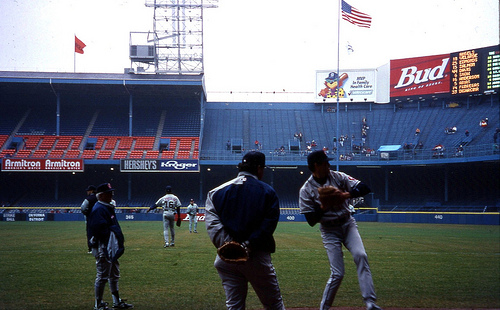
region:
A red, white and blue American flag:
[338, 0, 378, 33]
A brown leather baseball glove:
[212, 238, 253, 268]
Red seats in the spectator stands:
[2, 130, 204, 165]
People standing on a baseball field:
[2, 143, 499, 308]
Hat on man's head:
[303, 145, 337, 179]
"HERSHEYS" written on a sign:
[120, 154, 160, 176]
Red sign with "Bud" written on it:
[388, 51, 452, 101]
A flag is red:
[68, 28, 90, 75]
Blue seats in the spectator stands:
[202, 101, 498, 161]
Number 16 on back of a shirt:
[161, 197, 180, 216]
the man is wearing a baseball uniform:
[188, 140, 423, 302]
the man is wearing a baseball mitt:
[202, 222, 262, 299]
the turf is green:
[372, 232, 450, 295]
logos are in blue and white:
[121, 154, 216, 206]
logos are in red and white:
[6, 154, 125, 202]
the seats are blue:
[388, 186, 493, 269]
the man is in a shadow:
[70, 161, 179, 284]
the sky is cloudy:
[227, 15, 311, 102]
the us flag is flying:
[336, 2, 411, 75]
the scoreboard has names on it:
[441, 43, 498, 117]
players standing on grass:
[97, 144, 387, 303]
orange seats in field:
[27, 130, 198, 170]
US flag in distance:
[329, 2, 370, 114]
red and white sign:
[390, 46, 443, 108]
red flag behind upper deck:
[68, 36, 110, 77]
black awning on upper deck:
[5, 73, 201, 83]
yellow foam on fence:
[31, 205, 83, 217]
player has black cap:
[306, 146, 333, 171]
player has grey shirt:
[286, 163, 368, 230]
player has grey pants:
[290, 230, 390, 308]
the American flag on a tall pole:
[336, 0, 371, 29]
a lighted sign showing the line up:
[449, 44, 499, 100]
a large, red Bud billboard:
[388, 54, 450, 97]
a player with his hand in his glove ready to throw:
[299, 150, 375, 309]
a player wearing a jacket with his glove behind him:
[202, 150, 286, 308]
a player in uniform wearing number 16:
[144, 184, 181, 244]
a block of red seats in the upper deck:
[2, 133, 199, 159]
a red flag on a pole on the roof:
[73, 35, 85, 73]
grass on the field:
[2, 219, 498, 309]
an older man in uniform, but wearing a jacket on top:
[90, 182, 137, 309]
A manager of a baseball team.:
[81, 149, 170, 308]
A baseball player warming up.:
[290, 147, 415, 307]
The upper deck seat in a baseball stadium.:
[9, 113, 208, 194]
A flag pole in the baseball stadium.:
[333, 1, 352, 196]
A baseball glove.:
[210, 240, 255, 270]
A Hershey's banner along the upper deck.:
[120, 160, 156, 171]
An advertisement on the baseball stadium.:
[315, 68, 380, 100]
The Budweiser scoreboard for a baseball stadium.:
[388, 40, 496, 100]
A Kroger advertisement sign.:
[158, 158, 195, 169]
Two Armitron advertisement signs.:
[3, 156, 84, 173]